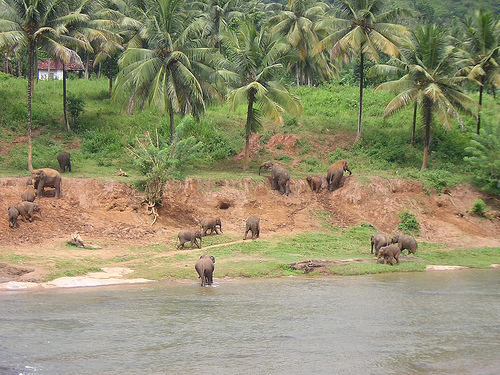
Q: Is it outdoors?
A: Yes, it is outdoors.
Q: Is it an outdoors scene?
A: Yes, it is outdoors.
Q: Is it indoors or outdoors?
A: It is outdoors.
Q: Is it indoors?
A: No, it is outdoors.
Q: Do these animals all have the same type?
A: Yes, all the animals are elephants.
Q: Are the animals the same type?
A: Yes, all the animals are elephants.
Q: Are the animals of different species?
A: No, all the animals are elephants.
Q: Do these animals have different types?
A: No, all the animals are elephants.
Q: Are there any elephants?
A: Yes, there is an elephant.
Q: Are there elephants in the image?
A: Yes, there is an elephant.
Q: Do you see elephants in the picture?
A: Yes, there is an elephant.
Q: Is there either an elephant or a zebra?
A: Yes, there is an elephant.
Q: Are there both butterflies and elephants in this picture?
A: No, there is an elephant but no butterflies.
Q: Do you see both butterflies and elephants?
A: No, there is an elephant but no butterflies.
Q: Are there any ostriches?
A: No, there are no ostriches.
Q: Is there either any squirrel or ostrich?
A: No, there are no ostriches or squirrels.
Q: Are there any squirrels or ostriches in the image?
A: No, there are no ostriches or squirrels.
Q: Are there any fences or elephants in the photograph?
A: Yes, there is an elephant.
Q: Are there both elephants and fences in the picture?
A: No, there is an elephant but no fences.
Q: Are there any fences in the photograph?
A: No, there are no fences.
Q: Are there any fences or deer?
A: No, there are no fences or deer.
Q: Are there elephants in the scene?
A: Yes, there is an elephant.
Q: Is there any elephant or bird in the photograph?
A: Yes, there is an elephant.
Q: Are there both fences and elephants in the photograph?
A: No, there is an elephant but no fences.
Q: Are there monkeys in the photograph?
A: No, there are no monkeys.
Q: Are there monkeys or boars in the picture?
A: No, there are no monkeys or boars.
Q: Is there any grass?
A: Yes, there is grass.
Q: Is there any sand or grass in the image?
A: Yes, there is grass.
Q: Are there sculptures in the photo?
A: No, there are no sculptures.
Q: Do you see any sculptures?
A: No, there are no sculptures.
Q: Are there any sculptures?
A: No, there are no sculptures.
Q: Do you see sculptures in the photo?
A: No, there are no sculptures.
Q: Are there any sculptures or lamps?
A: No, there are no sculptures or lamps.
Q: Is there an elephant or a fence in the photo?
A: Yes, there is an elephant.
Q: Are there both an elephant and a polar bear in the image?
A: No, there is an elephant but no polar bears.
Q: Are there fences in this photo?
A: No, there are no fences.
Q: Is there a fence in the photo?
A: No, there are no fences.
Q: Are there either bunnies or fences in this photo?
A: No, there are no fences or bunnies.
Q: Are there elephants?
A: Yes, there is an elephant.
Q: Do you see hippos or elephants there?
A: Yes, there is an elephant.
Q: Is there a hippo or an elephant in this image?
A: Yes, there is an elephant.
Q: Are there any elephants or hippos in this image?
A: Yes, there is an elephant.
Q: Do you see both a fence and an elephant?
A: No, there is an elephant but no fences.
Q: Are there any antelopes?
A: No, there are no antelopes.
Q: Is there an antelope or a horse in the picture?
A: No, there are no antelopes or horses.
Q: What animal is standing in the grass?
A: The elephant is standing in the grass.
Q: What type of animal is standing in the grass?
A: The animal is an elephant.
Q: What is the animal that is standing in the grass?
A: The animal is an elephant.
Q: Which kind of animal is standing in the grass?
A: The animal is an elephant.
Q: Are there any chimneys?
A: No, there are no chimneys.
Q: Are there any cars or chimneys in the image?
A: No, there are no chimneys or cars.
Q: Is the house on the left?
A: Yes, the house is on the left of the image.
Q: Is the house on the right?
A: No, the house is on the left of the image.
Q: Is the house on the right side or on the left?
A: The house is on the left of the image.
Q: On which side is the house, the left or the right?
A: The house is on the left of the image.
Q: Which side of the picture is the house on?
A: The house is on the left of the image.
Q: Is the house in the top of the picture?
A: Yes, the house is in the top of the image.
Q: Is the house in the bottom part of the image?
A: No, the house is in the top of the image.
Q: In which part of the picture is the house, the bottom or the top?
A: The house is in the top of the image.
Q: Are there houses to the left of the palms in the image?
A: Yes, there is a house to the left of the palms.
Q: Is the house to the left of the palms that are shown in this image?
A: Yes, the house is to the left of the palms.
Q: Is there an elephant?
A: Yes, there is an elephant.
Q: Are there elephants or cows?
A: Yes, there is an elephant.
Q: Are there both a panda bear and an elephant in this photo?
A: No, there is an elephant but no pandas.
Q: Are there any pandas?
A: No, there are no pandas.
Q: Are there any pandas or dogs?
A: No, there are no pandas or dogs.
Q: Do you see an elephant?
A: Yes, there is an elephant.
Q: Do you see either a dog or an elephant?
A: Yes, there is an elephant.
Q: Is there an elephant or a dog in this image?
A: Yes, there is an elephant.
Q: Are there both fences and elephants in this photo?
A: No, there is an elephant but no fences.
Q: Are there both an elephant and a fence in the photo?
A: No, there is an elephant but no fences.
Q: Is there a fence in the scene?
A: No, there are no fences.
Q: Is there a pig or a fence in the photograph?
A: No, there are no fences or pigs.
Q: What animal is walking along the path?
A: The animal is an elephant.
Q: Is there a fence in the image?
A: No, there are no fences.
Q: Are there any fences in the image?
A: No, there are no fences.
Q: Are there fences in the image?
A: No, there are no fences.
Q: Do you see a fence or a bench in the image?
A: No, there are no fences or benches.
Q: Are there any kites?
A: No, there are no kites.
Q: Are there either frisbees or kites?
A: No, there are no kites or frisbees.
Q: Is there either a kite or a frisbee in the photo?
A: No, there are no kites or frisbees.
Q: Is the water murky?
A: Yes, the water is murky.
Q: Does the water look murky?
A: Yes, the water is murky.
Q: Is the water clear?
A: No, the water is murky.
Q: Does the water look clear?
A: No, the water is murky.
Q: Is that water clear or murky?
A: The water is murky.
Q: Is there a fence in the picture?
A: No, there are no fences.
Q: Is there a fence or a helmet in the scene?
A: No, there are no fences or helmets.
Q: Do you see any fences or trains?
A: No, there are no fences or trains.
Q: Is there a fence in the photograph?
A: No, there are no fences.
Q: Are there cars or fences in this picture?
A: No, there are no fences or cars.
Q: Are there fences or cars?
A: No, there are no fences or cars.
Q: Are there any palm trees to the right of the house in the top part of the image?
A: Yes, there are palm trees to the right of the house.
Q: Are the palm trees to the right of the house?
A: Yes, the palm trees are to the right of the house.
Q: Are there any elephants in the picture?
A: Yes, there is an elephant.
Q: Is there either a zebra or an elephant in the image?
A: Yes, there is an elephant.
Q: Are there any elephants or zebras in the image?
A: Yes, there is an elephant.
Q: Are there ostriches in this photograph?
A: No, there are no ostriches.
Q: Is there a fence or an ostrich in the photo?
A: No, there are no ostriches or fences.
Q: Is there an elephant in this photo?
A: Yes, there is an elephant.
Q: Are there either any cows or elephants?
A: Yes, there is an elephant.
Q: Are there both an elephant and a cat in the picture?
A: No, there is an elephant but no cats.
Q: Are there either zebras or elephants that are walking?
A: Yes, the elephant is walking.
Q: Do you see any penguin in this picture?
A: No, there are no penguins.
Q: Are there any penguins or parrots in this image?
A: No, there are no penguins or parrots.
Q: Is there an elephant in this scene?
A: Yes, there is an elephant.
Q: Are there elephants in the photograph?
A: Yes, there is an elephant.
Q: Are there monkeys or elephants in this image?
A: Yes, there is an elephant.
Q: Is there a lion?
A: No, there are no lions.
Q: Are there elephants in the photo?
A: Yes, there is an elephant.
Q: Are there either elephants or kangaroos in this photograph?
A: Yes, there is an elephant.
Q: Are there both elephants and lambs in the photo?
A: No, there is an elephant but no lambs.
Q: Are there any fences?
A: No, there are no fences.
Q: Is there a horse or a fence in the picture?
A: No, there are no fences or horses.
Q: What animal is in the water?
A: The elephant is in the water.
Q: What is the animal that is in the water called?
A: The animal is an elephant.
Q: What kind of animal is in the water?
A: The animal is an elephant.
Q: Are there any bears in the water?
A: No, there is an elephant in the water.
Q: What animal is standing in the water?
A: The elephant is standing in the water.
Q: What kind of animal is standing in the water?
A: The animal is an elephant.